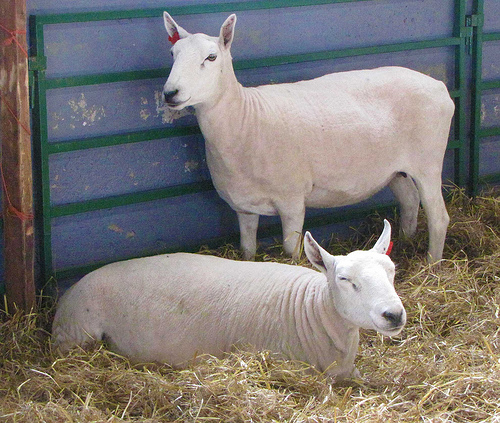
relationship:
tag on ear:
[169, 33, 188, 46] [155, 3, 195, 49]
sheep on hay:
[51, 237, 430, 377] [28, 338, 256, 422]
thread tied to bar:
[4, 102, 38, 139] [3, 5, 50, 336]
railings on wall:
[46, 18, 132, 121] [42, 19, 196, 240]